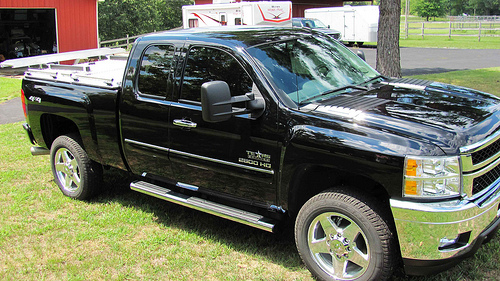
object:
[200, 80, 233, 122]
mirror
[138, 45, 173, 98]
window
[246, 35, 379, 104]
window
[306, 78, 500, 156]
hood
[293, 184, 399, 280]
wheel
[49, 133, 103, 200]
wheel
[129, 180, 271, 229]
step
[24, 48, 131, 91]
bed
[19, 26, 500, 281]
pickup truck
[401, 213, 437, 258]
grass surface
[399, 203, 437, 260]
metallic surface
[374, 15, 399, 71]
tree trunk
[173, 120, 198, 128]
door handle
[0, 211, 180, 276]
grass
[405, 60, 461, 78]
shadow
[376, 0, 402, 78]
tree